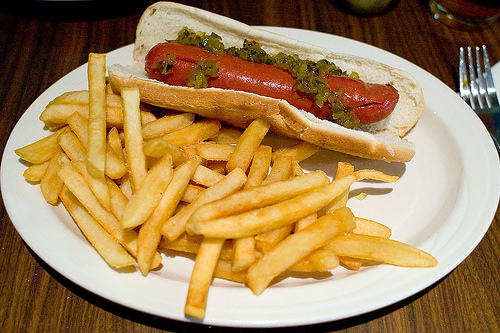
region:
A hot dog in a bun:
[118, 2, 426, 159]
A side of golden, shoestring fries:
[28, 72, 429, 312]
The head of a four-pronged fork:
[456, 43, 498, 119]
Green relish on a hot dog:
[178, 26, 336, 98]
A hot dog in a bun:
[143, 36, 399, 123]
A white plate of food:
[1, 23, 498, 317]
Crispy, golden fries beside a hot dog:
[53, 109, 316, 270]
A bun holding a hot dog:
[106, 3, 421, 168]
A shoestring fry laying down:
[87, 53, 106, 163]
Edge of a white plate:
[436, 98, 491, 174]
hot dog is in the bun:
[138, 36, 400, 126]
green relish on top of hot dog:
[152, 24, 364, 128]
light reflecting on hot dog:
[159, 49, 385, 114]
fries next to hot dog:
[14, 51, 440, 318]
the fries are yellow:
[4, 52, 439, 320]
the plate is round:
[2, 21, 499, 326]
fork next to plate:
[452, 35, 498, 152]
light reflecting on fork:
[454, 44, 497, 142]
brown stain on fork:
[457, 71, 472, 89]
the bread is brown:
[106, 76, 418, 168]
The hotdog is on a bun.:
[107, 0, 427, 159]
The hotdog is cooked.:
[106, 1, 434, 165]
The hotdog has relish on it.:
[103, 0, 438, 165]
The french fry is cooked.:
[76, 48, 112, 178]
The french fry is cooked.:
[116, 84, 154, 193]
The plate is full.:
[3, 0, 498, 329]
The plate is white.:
[0, 13, 499, 328]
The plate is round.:
[1, 3, 498, 332]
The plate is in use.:
[1, 1, 496, 331]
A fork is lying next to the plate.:
[0, 0, 499, 331]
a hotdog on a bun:
[143, 20, 378, 141]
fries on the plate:
[40, 73, 404, 290]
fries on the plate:
[42, 140, 339, 254]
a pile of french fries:
[36, 76, 331, 325]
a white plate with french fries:
[26, 72, 274, 332]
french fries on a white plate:
[21, 74, 293, 315]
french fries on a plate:
[28, 65, 285, 317]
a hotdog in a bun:
[111, 7, 479, 173]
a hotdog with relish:
[120, 12, 438, 164]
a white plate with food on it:
[28, 26, 464, 306]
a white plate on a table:
[41, 23, 495, 316]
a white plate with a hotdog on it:
[41, 21, 441, 199]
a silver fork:
[435, 23, 497, 128]